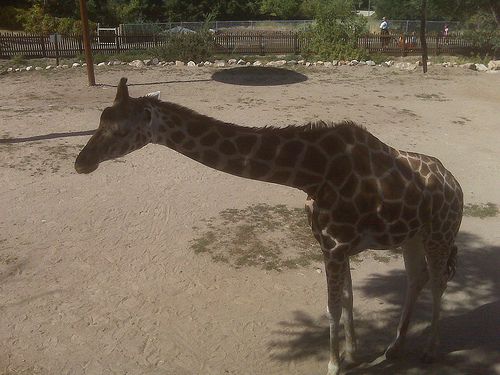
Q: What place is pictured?
A: It is a zoo.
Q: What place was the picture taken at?
A: It was taken at the zoo.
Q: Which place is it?
A: It is a zoo.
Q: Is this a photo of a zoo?
A: Yes, it is showing a zoo.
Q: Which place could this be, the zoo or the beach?
A: It is the zoo.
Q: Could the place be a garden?
A: No, it is a zoo.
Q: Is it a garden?
A: No, it is a zoo.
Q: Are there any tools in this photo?
A: No, there are no tools.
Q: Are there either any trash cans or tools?
A: No, there are no tools or trash cans.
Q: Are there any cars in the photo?
A: No, there are no cars.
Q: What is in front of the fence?
A: The trees are in front of the fence.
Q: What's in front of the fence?
A: The trees are in front of the fence.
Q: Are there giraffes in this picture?
A: Yes, there is a giraffe.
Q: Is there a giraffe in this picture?
A: Yes, there is a giraffe.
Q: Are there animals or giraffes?
A: Yes, there is a giraffe.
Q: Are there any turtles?
A: No, there are no turtles.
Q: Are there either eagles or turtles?
A: No, there are no turtles or eagles.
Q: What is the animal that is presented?
A: The animal is a giraffe.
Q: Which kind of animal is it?
A: The animal is a giraffe.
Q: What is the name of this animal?
A: That is a giraffe.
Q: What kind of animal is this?
A: That is a giraffe.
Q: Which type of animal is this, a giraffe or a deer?
A: That is a giraffe.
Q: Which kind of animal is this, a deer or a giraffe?
A: That is a giraffe.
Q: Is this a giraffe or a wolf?
A: This is a giraffe.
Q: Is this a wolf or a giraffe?
A: This is a giraffe.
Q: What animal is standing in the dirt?
A: The giraffe is standing in the dirt.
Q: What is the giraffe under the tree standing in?
A: The giraffe is standing in the dirt.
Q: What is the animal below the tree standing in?
A: The giraffe is standing in the dirt.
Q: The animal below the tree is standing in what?
A: The giraffe is standing in the dirt.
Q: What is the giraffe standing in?
A: The giraffe is standing in the dirt.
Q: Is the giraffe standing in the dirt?
A: Yes, the giraffe is standing in the dirt.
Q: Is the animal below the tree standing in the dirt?
A: Yes, the giraffe is standing in the dirt.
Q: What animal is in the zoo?
A: The giraffe is in the zoo.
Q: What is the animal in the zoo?
A: The animal is a giraffe.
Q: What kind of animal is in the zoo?
A: The animal is a giraffe.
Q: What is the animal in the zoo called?
A: The animal is a giraffe.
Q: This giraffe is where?
A: The giraffe is in the zoo.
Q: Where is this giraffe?
A: The giraffe is in the zoo.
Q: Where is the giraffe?
A: The giraffe is in the zoo.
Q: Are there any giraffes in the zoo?
A: Yes, there is a giraffe in the zoo.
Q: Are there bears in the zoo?
A: No, there is a giraffe in the zoo.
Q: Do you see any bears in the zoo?
A: No, there is a giraffe in the zoo.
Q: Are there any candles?
A: No, there are no candles.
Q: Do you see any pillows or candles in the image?
A: No, there are no candles or pillows.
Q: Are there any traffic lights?
A: No, there are no traffic lights.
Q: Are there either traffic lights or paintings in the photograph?
A: No, there are no traffic lights or paintings.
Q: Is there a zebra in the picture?
A: No, there are no zebras.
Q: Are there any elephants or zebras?
A: No, there are no zebras or elephants.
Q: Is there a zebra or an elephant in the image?
A: No, there are no zebras or elephants.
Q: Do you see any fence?
A: Yes, there is a fence.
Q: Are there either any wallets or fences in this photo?
A: Yes, there is a fence.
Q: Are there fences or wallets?
A: Yes, there is a fence.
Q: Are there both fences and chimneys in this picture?
A: No, there is a fence but no chimneys.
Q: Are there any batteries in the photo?
A: No, there are no batteries.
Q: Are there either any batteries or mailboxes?
A: No, there are no batteries or mailboxes.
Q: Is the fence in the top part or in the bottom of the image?
A: The fence is in the top of the image.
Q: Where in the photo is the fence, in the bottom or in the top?
A: The fence is in the top of the image.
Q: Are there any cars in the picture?
A: No, there are no cars.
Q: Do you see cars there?
A: No, there are no cars.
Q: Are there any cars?
A: No, there are no cars.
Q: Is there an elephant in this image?
A: No, there are no elephants.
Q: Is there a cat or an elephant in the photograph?
A: No, there are no elephants or cats.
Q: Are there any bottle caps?
A: No, there are no bottle caps.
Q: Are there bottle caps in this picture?
A: No, there are no bottle caps.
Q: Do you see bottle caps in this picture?
A: No, there are no bottle caps.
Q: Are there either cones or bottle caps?
A: No, there are no bottle caps or cones.